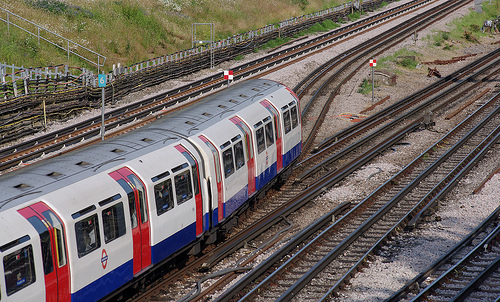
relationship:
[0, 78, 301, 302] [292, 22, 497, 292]
train on tracks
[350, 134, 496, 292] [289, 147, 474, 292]
gravel beside tracks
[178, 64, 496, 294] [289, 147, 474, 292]
gravel beside tracks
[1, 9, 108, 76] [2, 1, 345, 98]
rail going hill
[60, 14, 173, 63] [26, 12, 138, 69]
grass going hill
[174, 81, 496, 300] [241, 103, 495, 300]
gravel between track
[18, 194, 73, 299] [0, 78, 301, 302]
doors on train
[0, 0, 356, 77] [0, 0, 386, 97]
hill up hill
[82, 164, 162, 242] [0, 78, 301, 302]
door on train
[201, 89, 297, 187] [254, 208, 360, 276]
train on tracks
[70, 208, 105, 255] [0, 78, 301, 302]
windows on train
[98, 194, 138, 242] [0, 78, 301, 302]
windows on train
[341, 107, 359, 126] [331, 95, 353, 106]
spraypaint on ground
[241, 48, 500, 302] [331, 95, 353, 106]
track near ground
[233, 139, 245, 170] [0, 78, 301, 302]
window on train